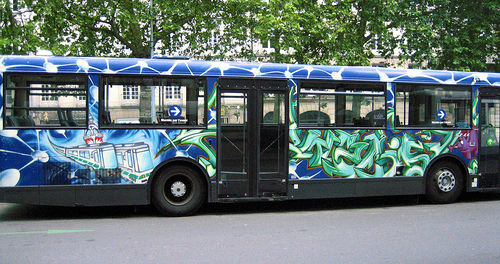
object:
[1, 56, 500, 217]
bus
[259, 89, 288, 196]
doors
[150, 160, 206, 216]
tire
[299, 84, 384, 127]
window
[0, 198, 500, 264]
road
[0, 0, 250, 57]
trees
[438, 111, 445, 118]
arrow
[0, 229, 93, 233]
arrow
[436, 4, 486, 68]
leaves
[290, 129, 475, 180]
graffiti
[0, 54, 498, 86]
roof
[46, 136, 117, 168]
train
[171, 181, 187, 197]
hubcap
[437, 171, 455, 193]
hubcap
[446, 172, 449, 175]
dots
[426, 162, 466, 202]
wheel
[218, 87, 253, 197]
back door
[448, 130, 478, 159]
image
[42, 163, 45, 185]
lines